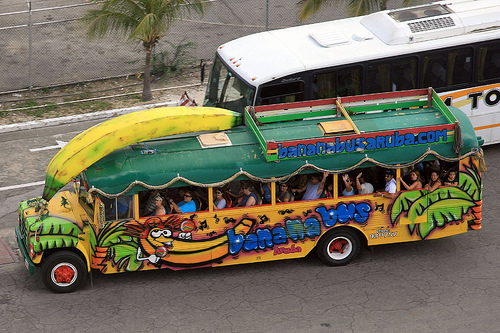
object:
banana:
[40, 103, 249, 202]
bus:
[14, 82, 500, 295]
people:
[442, 169, 460, 187]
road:
[1, 116, 500, 332]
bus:
[194, 0, 500, 158]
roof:
[76, 90, 482, 186]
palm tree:
[83, 0, 207, 104]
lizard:
[58, 194, 73, 212]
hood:
[16, 187, 87, 232]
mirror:
[198, 58, 208, 85]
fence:
[0, 0, 438, 95]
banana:
[132, 216, 258, 266]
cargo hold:
[240, 86, 463, 163]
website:
[275, 127, 448, 160]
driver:
[104, 194, 133, 222]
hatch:
[194, 131, 233, 149]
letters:
[467, 88, 500, 111]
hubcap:
[53, 263, 77, 284]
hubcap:
[328, 237, 349, 255]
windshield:
[200, 49, 256, 113]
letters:
[227, 199, 373, 256]